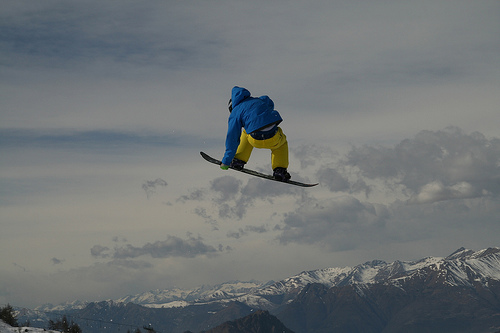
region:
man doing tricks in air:
[188, 72, 315, 210]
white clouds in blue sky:
[27, 22, 82, 64]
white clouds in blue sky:
[91, 31, 142, 66]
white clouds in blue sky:
[238, 22, 293, 66]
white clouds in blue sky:
[401, 52, 441, 73]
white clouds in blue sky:
[45, 49, 125, 109]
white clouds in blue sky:
[125, 99, 169, 120]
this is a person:
[211, 70, 311, 170]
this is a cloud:
[398, 125, 447, 175]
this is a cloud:
[341, 167, 390, 221]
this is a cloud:
[417, 121, 478, 193]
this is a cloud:
[109, 219, 231, 276]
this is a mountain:
[193, 261, 268, 316]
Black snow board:
[200, 150, 319, 189]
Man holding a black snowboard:
[196, 147, 319, 190]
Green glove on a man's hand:
[221, 162, 229, 169]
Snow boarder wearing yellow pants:
[231, 131, 291, 167]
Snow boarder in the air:
[198, 79, 318, 189]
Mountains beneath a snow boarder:
[3, 245, 498, 332]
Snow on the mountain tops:
[117, 256, 347, 304]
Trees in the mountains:
[2, 303, 85, 331]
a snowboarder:
[185, 78, 331, 194]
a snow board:
[249, 164, 268, 182]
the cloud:
[293, 204, 360, 238]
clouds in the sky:
[57, 113, 169, 164]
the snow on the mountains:
[280, 267, 347, 287]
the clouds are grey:
[349, 136, 489, 227]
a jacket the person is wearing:
[233, 96, 272, 123]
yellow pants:
[275, 139, 284, 168]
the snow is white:
[160, 289, 206, 306]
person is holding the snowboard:
[208, 155, 229, 170]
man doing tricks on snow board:
[185, 61, 326, 206]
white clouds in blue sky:
[27, 19, 87, 69]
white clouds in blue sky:
[364, 22, 416, 56]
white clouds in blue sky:
[88, 26, 122, 57]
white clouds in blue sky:
[104, 81, 168, 123]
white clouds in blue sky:
[54, 12, 135, 74]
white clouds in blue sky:
[410, 96, 447, 126]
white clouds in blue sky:
[354, 31, 402, 85]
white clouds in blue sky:
[234, 36, 316, 71]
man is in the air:
[176, 69, 336, 208]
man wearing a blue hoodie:
[215, 72, 289, 162]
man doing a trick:
[180, 83, 320, 216]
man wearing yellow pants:
[218, 122, 296, 176]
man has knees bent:
[228, 130, 298, 173]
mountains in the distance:
[97, 246, 496, 328]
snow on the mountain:
[288, 240, 498, 295]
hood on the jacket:
[223, 78, 253, 103]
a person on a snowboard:
[163, 80, 301, 185]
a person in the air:
[212, 64, 297, 180]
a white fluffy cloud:
[422, 168, 467, 205]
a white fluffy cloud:
[273, 163, 360, 249]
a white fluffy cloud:
[126, 229, 212, 268]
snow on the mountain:
[463, 246, 492, 288]